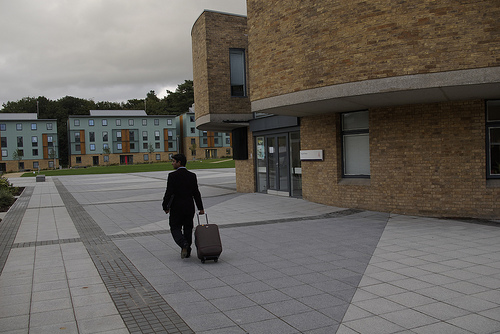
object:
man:
[162, 153, 204, 258]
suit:
[162, 167, 204, 246]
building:
[189, 2, 498, 223]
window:
[338, 111, 373, 180]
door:
[265, 133, 292, 196]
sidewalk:
[1, 172, 498, 333]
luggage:
[194, 213, 222, 263]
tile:
[347, 272, 381, 289]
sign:
[299, 149, 324, 162]